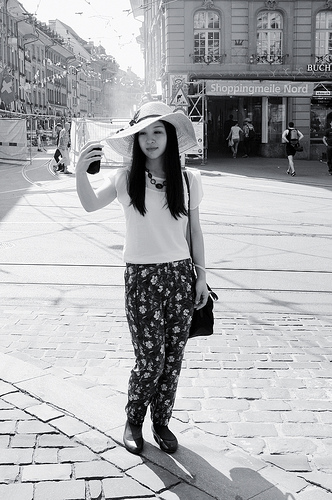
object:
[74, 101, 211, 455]
woman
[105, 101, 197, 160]
hat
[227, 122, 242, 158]
person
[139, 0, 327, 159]
store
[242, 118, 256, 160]
person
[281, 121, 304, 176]
person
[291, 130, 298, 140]
backpack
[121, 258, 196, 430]
pants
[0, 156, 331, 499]
plaza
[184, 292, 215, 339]
purse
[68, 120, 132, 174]
sheet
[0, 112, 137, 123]
line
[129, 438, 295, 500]
shadow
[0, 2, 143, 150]
buildings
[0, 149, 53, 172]
street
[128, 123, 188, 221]
hair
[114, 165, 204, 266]
blouse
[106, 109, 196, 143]
brim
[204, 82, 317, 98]
sign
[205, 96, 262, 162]
doorway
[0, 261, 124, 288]
shadows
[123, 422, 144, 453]
shoes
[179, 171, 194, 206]
shoulder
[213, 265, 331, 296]
tracks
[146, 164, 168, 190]
necklace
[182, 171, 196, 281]
strap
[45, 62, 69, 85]
flag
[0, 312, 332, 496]
street